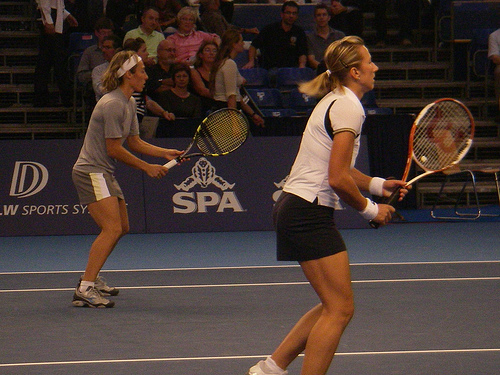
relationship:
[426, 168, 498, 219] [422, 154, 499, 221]
legs on chair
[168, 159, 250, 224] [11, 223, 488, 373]
advertisements lining court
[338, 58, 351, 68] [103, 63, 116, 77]
clip in hair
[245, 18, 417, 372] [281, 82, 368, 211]
woman wearing white t-shirt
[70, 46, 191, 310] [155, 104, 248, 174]
woman holding racket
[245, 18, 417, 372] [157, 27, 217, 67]
woman wearing shirt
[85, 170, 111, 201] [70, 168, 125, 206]
stripe on shorts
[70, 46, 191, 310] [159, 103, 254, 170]
woman holding tennis racket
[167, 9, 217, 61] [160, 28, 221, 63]
woman wearing shirt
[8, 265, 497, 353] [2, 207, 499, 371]
lines on court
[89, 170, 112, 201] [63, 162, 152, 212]
stripe on shorts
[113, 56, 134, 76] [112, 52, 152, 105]
headband on head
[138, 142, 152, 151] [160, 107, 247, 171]
hand holding racket